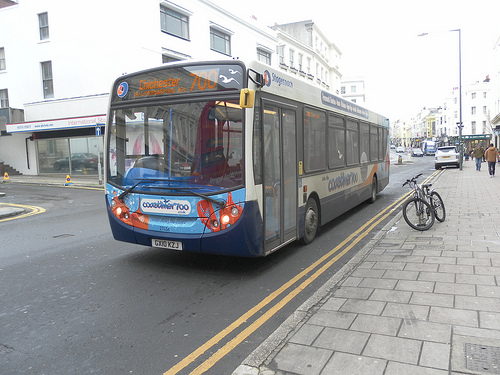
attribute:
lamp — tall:
[416, 23, 471, 137]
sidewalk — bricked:
[388, 157, 500, 368]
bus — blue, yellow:
[92, 50, 399, 274]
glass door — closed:
[257, 91, 310, 248]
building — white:
[5, 2, 373, 132]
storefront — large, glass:
[434, 131, 490, 161]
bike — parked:
[397, 169, 448, 233]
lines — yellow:
[152, 240, 352, 374]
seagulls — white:
[216, 67, 239, 90]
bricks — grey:
[291, 172, 495, 374]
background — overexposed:
[351, 87, 488, 153]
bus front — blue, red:
[93, 49, 266, 267]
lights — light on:
[209, 96, 290, 122]